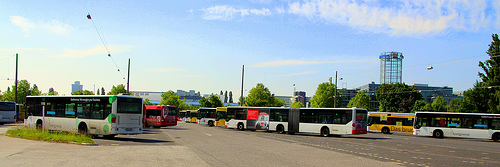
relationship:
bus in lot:
[24, 92, 147, 140] [2, 118, 499, 166]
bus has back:
[24, 92, 147, 140] [111, 93, 144, 136]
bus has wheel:
[267, 102, 368, 137] [320, 125, 331, 137]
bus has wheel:
[267, 102, 368, 137] [274, 123, 287, 135]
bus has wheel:
[414, 107, 499, 141] [433, 128, 445, 138]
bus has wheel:
[414, 107, 499, 141] [492, 129, 499, 141]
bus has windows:
[267, 102, 368, 137] [271, 109, 353, 126]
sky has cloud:
[2, 1, 499, 95] [200, 0, 493, 37]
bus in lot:
[267, 102, 368, 137] [2, 118, 499, 166]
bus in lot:
[414, 107, 499, 141] [2, 118, 499, 166]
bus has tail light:
[24, 92, 147, 140] [111, 116, 118, 124]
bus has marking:
[24, 92, 147, 140] [101, 123, 111, 136]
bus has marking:
[24, 92, 147, 140] [108, 92, 117, 104]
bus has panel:
[224, 106, 367, 137] [245, 108, 261, 121]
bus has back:
[145, 103, 180, 131] [161, 103, 180, 127]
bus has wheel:
[24, 92, 147, 140] [76, 119, 90, 136]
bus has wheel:
[24, 92, 147, 140] [35, 116, 45, 133]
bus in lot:
[367, 109, 416, 135] [2, 118, 499, 166]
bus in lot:
[214, 104, 227, 127] [2, 118, 499, 166]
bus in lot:
[197, 104, 217, 128] [2, 118, 499, 166]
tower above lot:
[376, 55, 406, 86] [2, 118, 499, 166]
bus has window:
[24, 92, 147, 140] [117, 95, 146, 115]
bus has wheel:
[367, 109, 416, 135] [380, 123, 391, 133]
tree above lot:
[309, 81, 344, 107] [2, 118, 499, 166]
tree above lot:
[242, 81, 284, 107] [2, 118, 499, 166]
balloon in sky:
[426, 64, 435, 74] [2, 1, 499, 95]